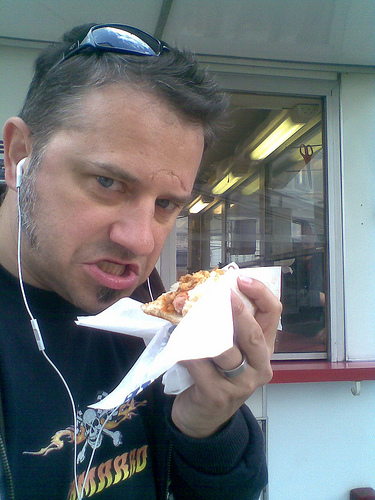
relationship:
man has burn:
[0, 17, 287, 500] [16, 139, 44, 232]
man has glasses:
[0, 17, 287, 500] [23, 23, 175, 89]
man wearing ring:
[0, 17, 287, 500] [169, 276, 281, 439]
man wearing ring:
[0, 17, 287, 500] [222, 355, 245, 377]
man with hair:
[0, 17, 287, 500] [20, 24, 220, 163]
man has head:
[0, 17, 287, 500] [2, 21, 224, 312]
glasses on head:
[23, 23, 175, 89] [2, 21, 224, 312]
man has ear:
[0, 17, 287, 500] [6, 116, 31, 186]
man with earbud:
[0, 17, 287, 500] [15, 154, 29, 187]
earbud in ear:
[15, 154, 29, 187] [6, 116, 31, 186]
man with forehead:
[0, 17, 287, 500] [65, 83, 205, 193]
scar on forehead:
[148, 166, 191, 192] [65, 83, 205, 193]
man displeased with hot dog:
[0, 17, 287, 500] [147, 268, 223, 323]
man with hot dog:
[0, 17, 287, 500] [147, 268, 223, 323]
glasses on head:
[62, 25, 174, 69] [2, 21, 224, 312]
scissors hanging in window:
[295, 141, 319, 191] [207, 118, 327, 263]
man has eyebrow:
[0, 17, 287, 500] [161, 191, 196, 201]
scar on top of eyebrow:
[148, 166, 191, 192] [161, 191, 196, 201]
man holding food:
[0, 17, 287, 500] [139, 267, 224, 327]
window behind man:
[174, 88, 328, 353] [0, 17, 287, 500]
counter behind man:
[267, 357, 368, 393] [27, 50, 271, 398]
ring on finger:
[217, 354, 249, 379] [183, 361, 235, 410]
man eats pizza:
[0, 17, 287, 500] [139, 263, 267, 362]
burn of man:
[15, 135, 49, 242] [0, 17, 287, 500]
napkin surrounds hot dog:
[61, 262, 282, 412] [140, 270, 216, 326]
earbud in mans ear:
[15, 154, 29, 187] [2, 115, 29, 190]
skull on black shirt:
[74, 399, 123, 452] [0, 281, 269, 495]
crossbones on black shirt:
[75, 429, 124, 460] [0, 281, 269, 495]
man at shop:
[275, 216, 334, 343] [116, 75, 351, 401]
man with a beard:
[0, 17, 287, 500] [96, 286, 121, 305]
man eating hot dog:
[0, 17, 287, 500] [132, 261, 219, 330]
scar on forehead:
[148, 166, 191, 192] [82, 99, 211, 195]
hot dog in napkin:
[139, 269, 216, 326] [61, 263, 289, 412]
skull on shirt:
[74, 399, 123, 452] [40, 299, 126, 400]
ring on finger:
[213, 343, 251, 379] [183, 361, 235, 410]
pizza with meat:
[147, 260, 257, 323] [163, 256, 213, 305]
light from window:
[252, 103, 328, 163] [175, 81, 343, 365]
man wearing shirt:
[0, 17, 287, 500] [0, 267, 150, 496]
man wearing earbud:
[0, 17, 287, 500] [15, 154, 29, 187]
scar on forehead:
[148, 166, 191, 192] [85, 87, 200, 197]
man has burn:
[17, 26, 261, 484] [16, 139, 44, 232]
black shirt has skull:
[0, 281, 269, 495] [75, 407, 108, 450]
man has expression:
[274, 214, 334, 343] [294, 238, 317, 259]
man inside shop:
[274, 214, 334, 343] [146, 50, 349, 337]